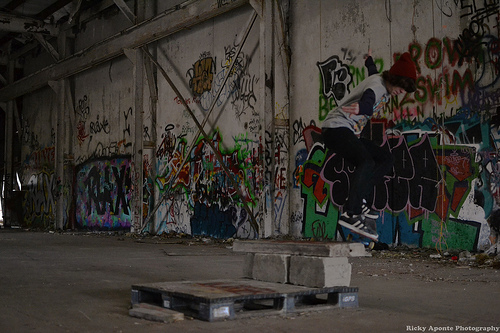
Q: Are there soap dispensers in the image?
A: No, there are no soap dispensers.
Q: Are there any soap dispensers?
A: No, there are no soap dispensers.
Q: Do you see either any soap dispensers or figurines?
A: No, there are no soap dispensers or figurines.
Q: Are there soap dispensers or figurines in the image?
A: No, there are no soap dispensers or figurines.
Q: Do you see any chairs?
A: No, there are no chairs.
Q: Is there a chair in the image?
A: No, there are no chairs.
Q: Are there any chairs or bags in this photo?
A: No, there are no chairs or bags.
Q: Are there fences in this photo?
A: No, there are no fences.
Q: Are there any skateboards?
A: Yes, there is a skateboard.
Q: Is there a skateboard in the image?
A: Yes, there is a skateboard.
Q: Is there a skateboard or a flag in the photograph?
A: Yes, there is a skateboard.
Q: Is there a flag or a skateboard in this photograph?
A: Yes, there is a skateboard.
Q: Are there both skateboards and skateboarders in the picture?
A: Yes, there are both a skateboard and a skateboarder.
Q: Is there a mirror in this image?
A: No, there are no mirrors.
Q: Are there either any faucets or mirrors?
A: No, there are no mirrors or faucets.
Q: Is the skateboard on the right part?
A: Yes, the skateboard is on the right of the image.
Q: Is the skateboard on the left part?
A: No, the skateboard is on the right of the image.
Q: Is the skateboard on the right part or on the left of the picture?
A: The skateboard is on the right of the image.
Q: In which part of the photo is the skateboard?
A: The skateboard is on the right of the image.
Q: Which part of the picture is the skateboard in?
A: The skateboard is on the right of the image.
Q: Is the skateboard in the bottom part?
A: Yes, the skateboard is in the bottom of the image.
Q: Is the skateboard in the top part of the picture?
A: No, the skateboard is in the bottom of the image.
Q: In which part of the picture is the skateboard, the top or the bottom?
A: The skateboard is in the bottom of the image.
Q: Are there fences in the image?
A: No, there are no fences.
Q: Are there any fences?
A: No, there are no fences.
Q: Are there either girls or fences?
A: No, there are no fences or girls.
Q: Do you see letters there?
A: Yes, there are letters.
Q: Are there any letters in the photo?
A: Yes, there are letters.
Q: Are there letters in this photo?
A: Yes, there are letters.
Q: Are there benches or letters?
A: Yes, there are letters.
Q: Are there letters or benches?
A: Yes, there are letters.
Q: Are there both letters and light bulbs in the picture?
A: No, there are letters but no light bulbs.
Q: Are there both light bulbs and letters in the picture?
A: No, there are letters but no light bulbs.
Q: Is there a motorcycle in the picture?
A: No, there are no motorcycles.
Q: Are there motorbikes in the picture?
A: No, there are no motorbikes.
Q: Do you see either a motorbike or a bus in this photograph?
A: No, there are no motorcycles or buses.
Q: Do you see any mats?
A: No, there are no mats.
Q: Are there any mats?
A: No, there are no mats.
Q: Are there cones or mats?
A: No, there are no mats or cones.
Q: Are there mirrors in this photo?
A: No, there are no mirrors.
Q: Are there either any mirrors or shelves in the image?
A: No, there are no mirrors or shelves.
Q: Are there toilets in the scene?
A: No, there are no toilets.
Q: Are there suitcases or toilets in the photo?
A: No, there are no toilets or suitcases.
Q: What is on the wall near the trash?
A: The graffiti is on the wall.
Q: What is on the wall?
A: The graffiti is on the wall.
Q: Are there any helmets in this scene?
A: No, there are no helmets.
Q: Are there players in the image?
A: No, there are no players.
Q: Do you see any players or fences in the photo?
A: No, there are no players or fences.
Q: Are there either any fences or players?
A: No, there are no players or fences.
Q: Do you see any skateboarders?
A: Yes, there is a skateboarder.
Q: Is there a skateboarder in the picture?
A: Yes, there is a skateboarder.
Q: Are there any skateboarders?
A: Yes, there is a skateboarder.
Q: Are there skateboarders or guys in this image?
A: Yes, there is a skateboarder.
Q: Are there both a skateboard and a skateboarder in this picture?
A: Yes, there are both a skateboarder and a skateboard.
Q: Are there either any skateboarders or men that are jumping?
A: Yes, the skateboarder is jumping.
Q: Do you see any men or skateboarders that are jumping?
A: Yes, the skateboarder is jumping.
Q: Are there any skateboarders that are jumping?
A: Yes, there is a skateboarder that is jumping.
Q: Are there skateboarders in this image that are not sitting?
A: Yes, there is a skateboarder that is jumping.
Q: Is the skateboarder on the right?
A: Yes, the skateboarder is on the right of the image.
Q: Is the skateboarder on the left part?
A: No, the skateboarder is on the right of the image.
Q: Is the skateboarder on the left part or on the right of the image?
A: The skateboarder is on the right of the image.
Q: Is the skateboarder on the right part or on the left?
A: The skateboarder is on the right of the image.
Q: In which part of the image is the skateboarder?
A: The skateboarder is on the right of the image.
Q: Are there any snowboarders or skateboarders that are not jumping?
A: No, there is a skateboarder but he is jumping.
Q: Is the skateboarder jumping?
A: Yes, the skateboarder is jumping.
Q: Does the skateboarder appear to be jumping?
A: Yes, the skateboarder is jumping.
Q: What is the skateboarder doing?
A: The skateboarder is jumping.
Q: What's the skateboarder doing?
A: The skateboarder is jumping.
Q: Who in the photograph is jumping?
A: The skateboarder is jumping.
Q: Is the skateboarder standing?
A: No, the skateboarder is jumping.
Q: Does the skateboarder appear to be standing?
A: No, the skateboarder is jumping.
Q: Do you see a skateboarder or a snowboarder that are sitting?
A: No, there is a skateboarder but he is jumping.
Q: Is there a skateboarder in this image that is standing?
A: No, there is a skateboarder but he is jumping.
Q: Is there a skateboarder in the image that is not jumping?
A: No, there is a skateboarder but he is jumping.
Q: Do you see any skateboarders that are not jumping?
A: No, there is a skateboarder but he is jumping.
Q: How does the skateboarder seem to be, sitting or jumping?
A: The skateboarder is jumping.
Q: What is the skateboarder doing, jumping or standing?
A: The skateboarder is jumping.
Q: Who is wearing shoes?
A: The skateboarder is wearing shoes.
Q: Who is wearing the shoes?
A: The skateboarder is wearing shoes.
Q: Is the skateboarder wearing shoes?
A: Yes, the skateboarder is wearing shoes.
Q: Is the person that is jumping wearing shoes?
A: Yes, the skateboarder is wearing shoes.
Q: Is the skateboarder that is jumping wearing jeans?
A: No, the skateboarder is wearing shoes.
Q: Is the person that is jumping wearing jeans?
A: No, the skateboarder is wearing shoes.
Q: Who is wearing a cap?
A: The skateboarder is wearing a cap.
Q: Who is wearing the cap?
A: The skateboarder is wearing a cap.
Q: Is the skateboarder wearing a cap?
A: Yes, the skateboarder is wearing a cap.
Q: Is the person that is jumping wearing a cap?
A: Yes, the skateboarder is wearing a cap.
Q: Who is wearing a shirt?
A: The skateboarder is wearing a shirt.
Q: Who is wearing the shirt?
A: The skateboarder is wearing a shirt.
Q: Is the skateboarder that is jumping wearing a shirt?
A: Yes, the skateboarder is wearing a shirt.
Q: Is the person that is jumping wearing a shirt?
A: Yes, the skateboarder is wearing a shirt.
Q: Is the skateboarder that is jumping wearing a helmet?
A: No, the skateboarder is wearing a shirt.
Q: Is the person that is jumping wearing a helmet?
A: No, the skateboarder is wearing a shirt.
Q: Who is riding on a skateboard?
A: The skateboarder is riding on a skateboard.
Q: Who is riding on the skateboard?
A: The skateboarder is riding on a skateboard.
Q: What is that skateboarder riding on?
A: The skateboarder is riding on a skateboard.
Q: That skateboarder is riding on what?
A: The skateboarder is riding on a skateboard.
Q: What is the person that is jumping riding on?
A: The skateboarder is riding on a skateboard.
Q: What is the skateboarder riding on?
A: The skateboarder is riding on a skateboard.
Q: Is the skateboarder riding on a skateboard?
A: Yes, the skateboarder is riding on a skateboard.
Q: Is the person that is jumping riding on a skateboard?
A: Yes, the skateboarder is riding on a skateboard.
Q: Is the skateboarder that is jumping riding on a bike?
A: No, the skateboarder is riding on a skateboard.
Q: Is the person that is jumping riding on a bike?
A: No, the skateboarder is riding on a skateboard.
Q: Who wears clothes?
A: The skateboarder wears clothes.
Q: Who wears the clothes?
A: The skateboarder wears clothes.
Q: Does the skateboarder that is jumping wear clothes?
A: Yes, the skateboarder wears clothes.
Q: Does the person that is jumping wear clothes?
A: Yes, the skateboarder wears clothes.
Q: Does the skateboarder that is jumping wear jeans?
A: No, the skateboarder wears clothes.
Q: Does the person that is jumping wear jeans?
A: No, the skateboarder wears clothes.